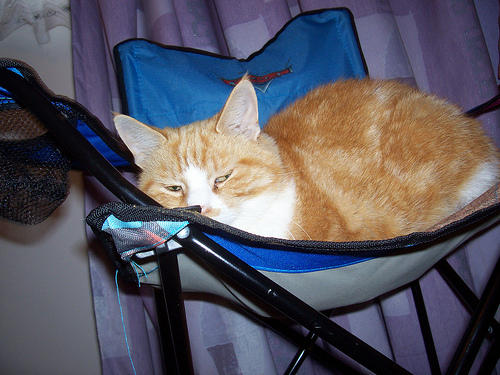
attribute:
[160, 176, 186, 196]
cat eyes — light green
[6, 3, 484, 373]
photo — jackson mingus's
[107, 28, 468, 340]
chair — blue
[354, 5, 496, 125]
curtain — purple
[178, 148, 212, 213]
spot — white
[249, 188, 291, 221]
spot — white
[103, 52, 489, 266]
cat — orange, white, furry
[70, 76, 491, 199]
cat — orange, white, furry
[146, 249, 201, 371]
seat leg — black